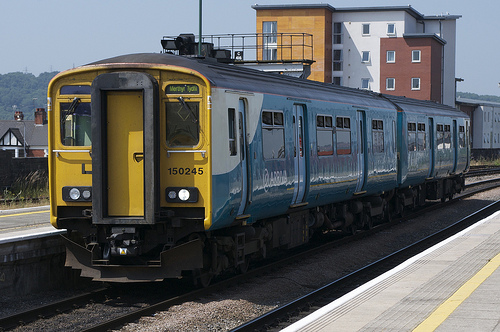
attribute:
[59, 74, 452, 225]
train — blue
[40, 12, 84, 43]
sky — blue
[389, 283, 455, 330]
ground — grey